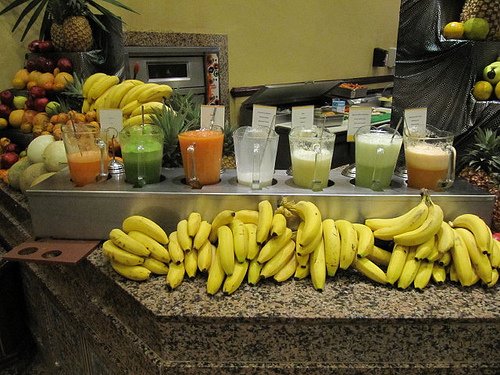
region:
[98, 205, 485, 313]
bananas on the counter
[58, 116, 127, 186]
the liquid is orange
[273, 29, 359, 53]
gold color on wall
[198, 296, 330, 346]
black and tan stone counter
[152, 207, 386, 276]
bunch of yellow bananas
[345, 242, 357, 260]
small brown stain on banana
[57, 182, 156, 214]
tall silver counter space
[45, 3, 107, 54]
big pineapple on shelf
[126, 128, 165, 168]
green liquid in bowl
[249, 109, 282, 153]
large silver stirrer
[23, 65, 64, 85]
juicy ripe red mango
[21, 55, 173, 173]
tropical fruits on shelf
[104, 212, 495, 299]
bunch of yellow bananas on counter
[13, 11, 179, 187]
fruit for smoothies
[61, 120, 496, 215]
orange green and white smoothies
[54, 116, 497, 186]
a row of smoothies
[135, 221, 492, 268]
several bananas on table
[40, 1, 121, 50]
a single pineapple sits up high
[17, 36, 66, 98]
a bunch of apples and oranges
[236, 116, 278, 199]
considering it is almost empty must be good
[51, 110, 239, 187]
orange and green smoothies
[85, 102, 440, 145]
signs behind each pitcher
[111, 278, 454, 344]
marble counter top below fruit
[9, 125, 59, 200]
some melons behind and left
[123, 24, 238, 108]
an oven in the wall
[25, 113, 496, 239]
Silver display tray full of pitchers of smoothies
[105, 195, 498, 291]
Numerous bunches of yellow bananas sitting underneath smoothie pitchers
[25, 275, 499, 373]
Marble granite counter with bunches of bananas sitting on it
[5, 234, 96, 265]
Wooden platform with two holes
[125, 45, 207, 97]
Stainless steel oven sitting behind a counter of smoothies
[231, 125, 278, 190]
Nearly empty pitcher sitting in the middle of a row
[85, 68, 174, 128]
Bunch of bananas sitting behind a row of smoothies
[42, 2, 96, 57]
Pair of pineapples sitting next to an oven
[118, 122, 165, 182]
Pitcher of dark green liquid to left of a pitcher of orange liquid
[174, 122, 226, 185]
A completely full pitcher of orange liquid